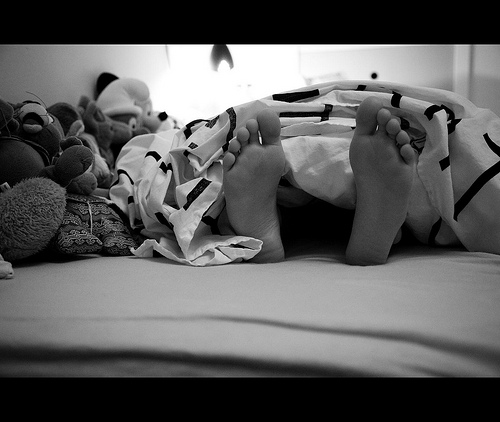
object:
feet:
[220, 109, 287, 262]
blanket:
[119, 79, 500, 264]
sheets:
[0, 251, 495, 378]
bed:
[0, 255, 500, 421]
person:
[174, 145, 425, 261]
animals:
[0, 95, 93, 183]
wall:
[0, 37, 172, 94]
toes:
[257, 108, 282, 145]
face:
[10, 101, 63, 151]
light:
[163, 69, 181, 78]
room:
[0, 5, 500, 422]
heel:
[246, 237, 284, 263]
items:
[60, 197, 131, 261]